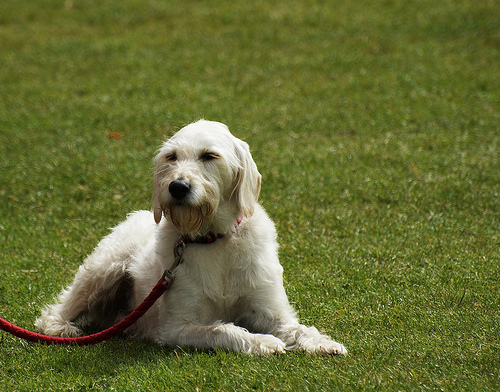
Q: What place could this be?
A: It is a field.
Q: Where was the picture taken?
A: It was taken at the field.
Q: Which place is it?
A: It is a field.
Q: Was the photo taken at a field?
A: Yes, it was taken in a field.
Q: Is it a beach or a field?
A: It is a field.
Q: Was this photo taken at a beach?
A: No, the picture was taken in a field.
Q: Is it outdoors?
A: Yes, it is outdoors.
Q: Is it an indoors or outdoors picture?
A: It is outdoors.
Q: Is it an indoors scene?
A: No, it is outdoors.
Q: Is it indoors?
A: No, it is outdoors.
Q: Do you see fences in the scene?
A: No, there are no fences.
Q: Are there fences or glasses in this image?
A: No, there are no fences or glasses.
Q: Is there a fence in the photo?
A: No, there are no fences.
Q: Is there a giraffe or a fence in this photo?
A: No, there are no fences or giraffes.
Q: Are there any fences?
A: No, there are no fences.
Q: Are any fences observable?
A: No, there are no fences.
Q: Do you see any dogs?
A: Yes, there is a dog.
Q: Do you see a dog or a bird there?
A: Yes, there is a dog.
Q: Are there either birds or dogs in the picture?
A: Yes, there is a dog.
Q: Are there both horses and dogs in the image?
A: No, there is a dog but no horses.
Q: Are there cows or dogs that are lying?
A: Yes, the dog is lying.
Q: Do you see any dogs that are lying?
A: Yes, there is a dog that is lying.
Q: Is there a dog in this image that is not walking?
A: Yes, there is a dog that is lying.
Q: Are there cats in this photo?
A: No, there are no cats.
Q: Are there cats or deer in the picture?
A: No, there are no cats or deer.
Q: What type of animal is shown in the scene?
A: The animal is a dog.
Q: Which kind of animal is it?
A: The animal is a dog.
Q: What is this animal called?
A: This is a dog.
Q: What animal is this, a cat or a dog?
A: This is a dog.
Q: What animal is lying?
A: The animal is a dog.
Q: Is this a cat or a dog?
A: This is a dog.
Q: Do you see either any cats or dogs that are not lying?
A: No, there is a dog but it is lying.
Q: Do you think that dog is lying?
A: Yes, the dog is lying.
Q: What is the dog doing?
A: The dog is lying.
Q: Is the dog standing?
A: No, the dog is lying.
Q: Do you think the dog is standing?
A: No, the dog is lying.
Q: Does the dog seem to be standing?
A: No, the dog is lying.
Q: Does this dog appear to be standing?
A: No, the dog is lying.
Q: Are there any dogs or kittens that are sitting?
A: No, there is a dog but it is lying.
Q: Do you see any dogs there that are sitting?
A: No, there is a dog but it is lying.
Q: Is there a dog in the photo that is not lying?
A: No, there is a dog but it is lying.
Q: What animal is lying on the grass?
A: The dog is lying on the grass.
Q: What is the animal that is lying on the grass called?
A: The animal is a dog.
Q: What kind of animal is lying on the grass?
A: The animal is a dog.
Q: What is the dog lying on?
A: The dog is lying on the grass.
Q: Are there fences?
A: No, there are no fences.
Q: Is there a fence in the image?
A: No, there are no fences.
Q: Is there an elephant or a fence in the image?
A: No, there are no fences or elephants.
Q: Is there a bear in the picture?
A: No, there are no bears.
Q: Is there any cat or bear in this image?
A: No, there are no bears or cats.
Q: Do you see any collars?
A: Yes, there is a collar.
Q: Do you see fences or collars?
A: Yes, there is a collar.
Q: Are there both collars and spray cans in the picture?
A: No, there is a collar but no spray cans.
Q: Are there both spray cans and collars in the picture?
A: No, there is a collar but no spray cans.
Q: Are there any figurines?
A: No, there are no figurines.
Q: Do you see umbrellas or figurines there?
A: No, there are no figurines or umbrellas.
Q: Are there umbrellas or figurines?
A: No, there are no figurines or umbrellas.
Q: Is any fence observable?
A: No, there are no fences.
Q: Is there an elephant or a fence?
A: No, there are no fences or elephants.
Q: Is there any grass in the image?
A: Yes, there is grass.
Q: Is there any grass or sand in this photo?
A: Yes, there is grass.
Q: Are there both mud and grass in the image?
A: No, there is grass but no mud.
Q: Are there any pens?
A: No, there are no pens.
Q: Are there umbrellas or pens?
A: No, there are no pens or umbrellas.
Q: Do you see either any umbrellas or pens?
A: No, there are no pens or umbrellas.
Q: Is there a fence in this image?
A: No, there are no fences.